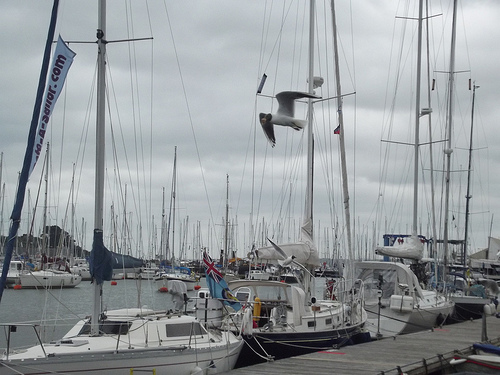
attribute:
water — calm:
[1, 267, 381, 350]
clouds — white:
[127, 49, 245, 190]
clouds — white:
[141, 117, 243, 212]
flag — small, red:
[200, 242, 241, 308]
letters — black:
[28, 33, 78, 187]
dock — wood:
[307, 340, 432, 361]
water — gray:
[8, 292, 78, 318]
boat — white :
[13, 281, 240, 370]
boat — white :
[333, 246, 448, 336]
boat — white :
[188, 246, 360, 358]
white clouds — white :
[363, 65, 385, 123]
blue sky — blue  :
[208, 67, 254, 97]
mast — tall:
[51, 13, 188, 157]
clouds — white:
[150, 14, 207, 72]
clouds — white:
[142, 16, 252, 161]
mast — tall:
[158, 182, 170, 270]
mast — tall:
[167, 145, 180, 272]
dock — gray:
[234, 310, 495, 374]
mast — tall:
[276, 28, 371, 221]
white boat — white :
[4, 298, 249, 373]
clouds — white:
[83, 25, 169, 75]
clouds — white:
[134, 92, 259, 172]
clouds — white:
[210, 24, 245, 125]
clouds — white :
[177, 29, 234, 60]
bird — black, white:
[225, 55, 360, 162]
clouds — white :
[75, 14, 488, 238]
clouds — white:
[9, 5, 498, 245]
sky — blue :
[5, 2, 495, 265]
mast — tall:
[403, 5, 438, 263]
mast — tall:
[227, 85, 263, 262]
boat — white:
[1, 295, 253, 375]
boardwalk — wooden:
[218, 314, 498, 373]